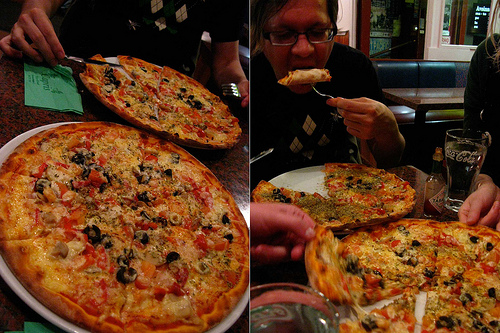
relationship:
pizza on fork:
[0, 54, 500, 331] [311, 82, 336, 101]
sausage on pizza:
[52, 241, 68, 255] [18, 96, 226, 331]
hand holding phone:
[207, 55, 248, 110] [220, 80, 240, 103]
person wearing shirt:
[230, 2, 419, 182] [230, 39, 388, 193]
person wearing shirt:
[446, 0, 498, 242] [453, 27, 496, 209]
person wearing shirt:
[2, 0, 267, 129] [46, 2, 249, 112]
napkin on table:
[22, 60, 84, 118] [5, 77, 30, 119]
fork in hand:
[309, 86, 332, 98] [323, 93, 398, 139]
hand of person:
[323, 93, 398, 139] [250, 0, 436, 182]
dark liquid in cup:
[445, 142, 482, 205] [444, 129, 492, 217]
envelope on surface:
[17, 50, 92, 115] [7, 34, 253, 294]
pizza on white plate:
[11, 121, 247, 322] [3, 124, 250, 327]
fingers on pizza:
[257, 182, 326, 266] [0, 107, 255, 320]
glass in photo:
[438, 122, 491, 217] [266, 7, 484, 330]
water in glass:
[252, 296, 332, 331] [438, 122, 491, 217]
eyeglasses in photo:
[269, 20, 331, 42] [260, 6, 483, 296]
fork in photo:
[309, 85, 335, 98] [10, 5, 177, 330]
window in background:
[348, 4, 491, 74] [261, 4, 484, 57]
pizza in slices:
[0, 54, 500, 331] [6, 110, 233, 329]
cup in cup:
[444, 129, 492, 217] [403, 109, 499, 225]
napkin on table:
[22, 60, 84, 118] [2, 36, 244, 331]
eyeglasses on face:
[262, 27, 339, 46] [254, 1, 338, 91]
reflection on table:
[205, 153, 269, 241] [381, 85, 465, 111]